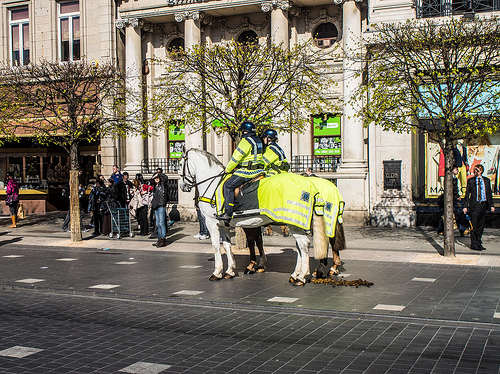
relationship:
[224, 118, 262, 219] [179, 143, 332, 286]
policeman on a horse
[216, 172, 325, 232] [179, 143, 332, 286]
blanket on a horse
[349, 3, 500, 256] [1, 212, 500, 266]
tree on sidewalk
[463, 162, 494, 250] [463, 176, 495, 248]
man in a suit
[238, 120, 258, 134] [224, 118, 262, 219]
helmet on a policeman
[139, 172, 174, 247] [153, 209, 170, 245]
person wearing jeans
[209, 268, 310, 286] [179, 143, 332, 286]
hooves on a horse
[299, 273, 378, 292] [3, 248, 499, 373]
horse droppings on street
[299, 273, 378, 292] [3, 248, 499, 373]
horse droppings on ground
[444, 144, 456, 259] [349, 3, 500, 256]
trunk of a tree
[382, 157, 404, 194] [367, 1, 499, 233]
plaque on building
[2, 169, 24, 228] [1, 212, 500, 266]
woman on sidewalk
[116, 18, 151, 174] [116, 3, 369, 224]
column on a building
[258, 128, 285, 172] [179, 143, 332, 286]
police officer on a horse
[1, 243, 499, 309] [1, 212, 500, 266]
tiles on a sidewalk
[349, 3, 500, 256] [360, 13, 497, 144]
tree with leaves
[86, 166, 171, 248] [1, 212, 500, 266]
people on sidewalk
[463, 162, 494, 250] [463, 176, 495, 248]
man wears a suit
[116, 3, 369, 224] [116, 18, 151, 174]
building has a column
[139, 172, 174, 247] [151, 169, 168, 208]
person wearing leather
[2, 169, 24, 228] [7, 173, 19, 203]
woman wears a sweater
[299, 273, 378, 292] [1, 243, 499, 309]
horse droppings on tiles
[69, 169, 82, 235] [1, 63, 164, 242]
base of a tree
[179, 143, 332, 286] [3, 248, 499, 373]
horse in street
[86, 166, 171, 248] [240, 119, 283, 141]
people wearing helmets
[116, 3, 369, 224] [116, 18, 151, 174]
building with a column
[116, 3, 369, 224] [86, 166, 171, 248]
building behind people